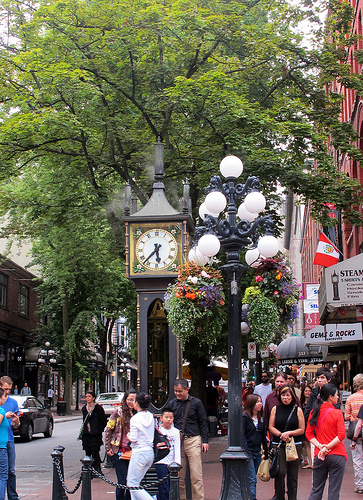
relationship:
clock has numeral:
[135, 228, 178, 272] [145, 230, 154, 241]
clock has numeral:
[135, 228, 178, 272] [153, 230, 162, 239]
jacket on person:
[128, 410, 155, 452] [126, 391, 154, 498]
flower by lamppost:
[174, 269, 231, 306] [187, 153, 280, 498]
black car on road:
[9, 393, 54, 439] [2, 411, 108, 495]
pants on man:
[169, 431, 212, 497] [162, 378, 215, 499]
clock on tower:
[127, 222, 185, 274] [120, 136, 190, 428]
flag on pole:
[313, 228, 340, 268] [317, 228, 346, 257]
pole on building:
[317, 228, 346, 257] [298, 1, 354, 408]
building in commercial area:
[249, 180, 357, 368] [16, 216, 358, 467]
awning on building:
[272, 328, 331, 369] [249, 180, 357, 368]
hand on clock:
[155, 241, 160, 265] [134, 221, 183, 267]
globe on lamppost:
[218, 152, 244, 179] [187, 153, 280, 498]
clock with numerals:
[135, 228, 178, 272] [136, 226, 179, 273]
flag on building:
[313, 226, 344, 271] [286, 1, 361, 358]